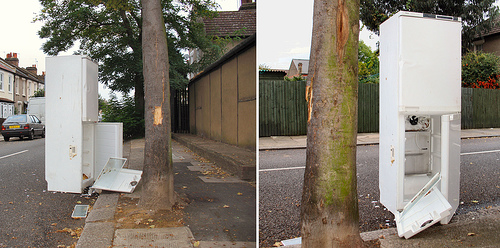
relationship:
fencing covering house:
[258, 77, 306, 137] [283, 56, 313, 81]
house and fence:
[282, 59, 312, 84] [261, 78, 499, 138]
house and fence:
[461, 9, 498, 85] [261, 78, 499, 138]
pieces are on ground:
[64, 150, 143, 208] [4, 137, 255, 245]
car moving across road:
[2, 111, 44, 143] [2, 131, 99, 247]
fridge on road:
[43, 54, 144, 194] [0, 124, 107, 246]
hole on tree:
[335, 1, 353, 49] [309, 7, 376, 247]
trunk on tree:
[123, 8, 185, 218] [33, 0, 244, 200]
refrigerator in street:
[379, 10, 466, 233] [3, 148, 42, 235]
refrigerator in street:
[379, 10, 466, 233] [470, 141, 495, 216]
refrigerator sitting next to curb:
[379, 10, 466, 233] [360, 210, 497, 247]